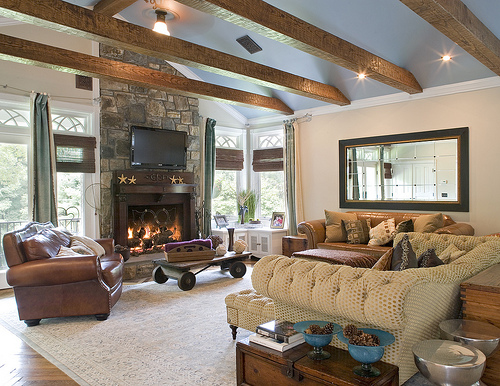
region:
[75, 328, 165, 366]
items in the living room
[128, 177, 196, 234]
items in the living roomitems in the living room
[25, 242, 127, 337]
items in the living room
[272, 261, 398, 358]
items in the living room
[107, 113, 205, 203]
items in the living room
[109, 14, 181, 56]
items in the living room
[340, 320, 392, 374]
a blue bowl with pinecones in it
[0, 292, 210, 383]
a rug on the floor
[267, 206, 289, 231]
a framed picture on a table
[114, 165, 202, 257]
a large wood fireplace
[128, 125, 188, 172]
a flat screen tv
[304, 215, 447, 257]
a brown leather couch with pillows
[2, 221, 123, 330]
a brown leather chair with pillows on it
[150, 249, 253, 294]
a wagon in front of a fireplace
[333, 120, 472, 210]
a large mirror hanging on a wall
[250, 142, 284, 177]
a brown shade hanging on a window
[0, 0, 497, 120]
Wooden beams are on the ceiling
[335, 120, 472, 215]
A mirror hanging on the wall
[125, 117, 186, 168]
A black flat screen TV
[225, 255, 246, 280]
A black round wheel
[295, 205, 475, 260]
Many pillows on a couch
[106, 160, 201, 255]
A fire is lit in a fireplace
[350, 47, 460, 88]
Two lights are turned on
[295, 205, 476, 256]
A brown and leather couch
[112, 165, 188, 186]
Four stars on a fireplace mantle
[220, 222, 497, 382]
Pillows are on a white couch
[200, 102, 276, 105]
the view of a white wall and chairs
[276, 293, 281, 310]
the view of a white wall and chairs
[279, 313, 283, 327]
the view of a white wall and chairs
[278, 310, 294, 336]
the view of a white wall and chairs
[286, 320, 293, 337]
the view of a white wall and chairs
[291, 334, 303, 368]
the view of a white wall and chairs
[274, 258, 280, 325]
the view of a white wall and chairs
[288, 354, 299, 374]
the view of a white wall and chairs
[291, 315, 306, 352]
the view of a white wall and chairs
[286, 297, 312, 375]
the view of a white wall and chairs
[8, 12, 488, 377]
living room in airy space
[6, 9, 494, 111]
wooden beams across blue ceiling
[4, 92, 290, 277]
burning fireplace in the middle of glass walls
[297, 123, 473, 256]
rectangular mirror over brown leather sofa